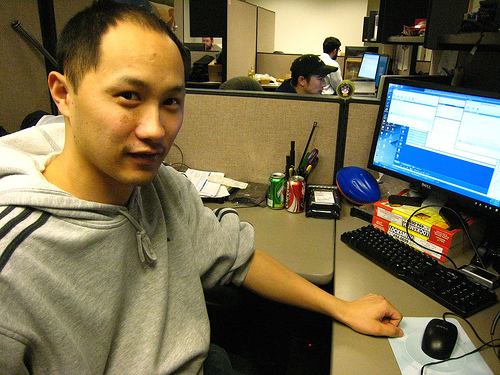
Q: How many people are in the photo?
A: 5.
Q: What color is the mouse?
A: Black.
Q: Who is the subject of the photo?
A: The man.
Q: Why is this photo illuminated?
A: Light fixtures.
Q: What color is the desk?
A: Brown.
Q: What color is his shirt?
A: Gray.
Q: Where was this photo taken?
A: In an office cubicle.